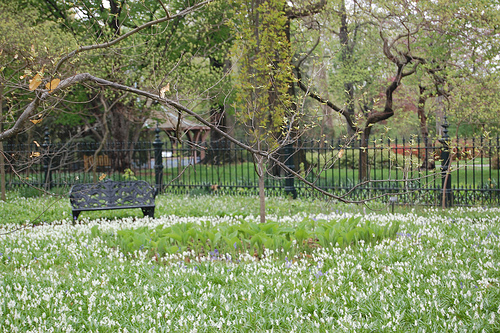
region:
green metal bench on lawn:
[68, 175, 158, 223]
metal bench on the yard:
[66, 175, 158, 221]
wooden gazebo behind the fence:
[80, 104, 212, 168]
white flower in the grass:
[12, 254, 489, 328]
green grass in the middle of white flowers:
[79, 213, 419, 272]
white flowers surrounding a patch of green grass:
[38, 215, 458, 314]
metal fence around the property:
[2, 120, 496, 208]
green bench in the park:
[36, 151, 183, 242]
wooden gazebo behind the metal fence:
[70, 15, 210, 166]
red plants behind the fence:
[387, 136, 477, 166]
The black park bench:
[65, 174, 160, 224]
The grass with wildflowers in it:
[1, 188, 498, 331]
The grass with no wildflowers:
[1, 146, 499, 204]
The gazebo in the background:
[124, 101, 209, 167]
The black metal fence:
[0, 123, 498, 204]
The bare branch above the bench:
[0, 1, 468, 203]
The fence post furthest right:
[433, 111, 457, 208]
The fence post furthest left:
[38, 120, 53, 197]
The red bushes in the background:
[392, 136, 493, 163]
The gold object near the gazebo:
[78, 148, 115, 173]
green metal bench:
[65, 178, 162, 221]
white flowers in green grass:
[1, 211, 499, 330]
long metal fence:
[0, 113, 499, 195]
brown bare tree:
[293, 21, 423, 196]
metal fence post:
[430, 103, 457, 205]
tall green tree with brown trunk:
[3, 1, 216, 174]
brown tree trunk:
[356, 136, 372, 195]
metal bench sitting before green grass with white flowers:
[1, 175, 498, 332]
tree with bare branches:
[224, 1, 329, 224]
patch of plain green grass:
[121, 227, 283, 247]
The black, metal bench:
[65, 173, 160, 221]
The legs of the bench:
[68, 210, 155, 221]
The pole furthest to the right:
[435, 118, 456, 208]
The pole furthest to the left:
[35, 131, 56, 199]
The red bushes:
[393, 133, 485, 164]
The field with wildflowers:
[0, 185, 498, 332]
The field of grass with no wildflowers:
[0, 158, 495, 204]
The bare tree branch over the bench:
[0, 0, 485, 212]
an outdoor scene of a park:
[1, 1, 498, 332]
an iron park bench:
[68, 179, 158, 218]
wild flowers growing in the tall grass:
[1, 214, 498, 331]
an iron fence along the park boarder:
[5, 136, 499, 203]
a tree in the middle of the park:
[232, 0, 302, 225]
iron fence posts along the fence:
[152, 119, 166, 188]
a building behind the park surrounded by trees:
[3, 63, 208, 176]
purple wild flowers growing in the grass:
[206, 243, 225, 264]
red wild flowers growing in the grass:
[299, 236, 318, 256]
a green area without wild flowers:
[116, 219, 385, 244]